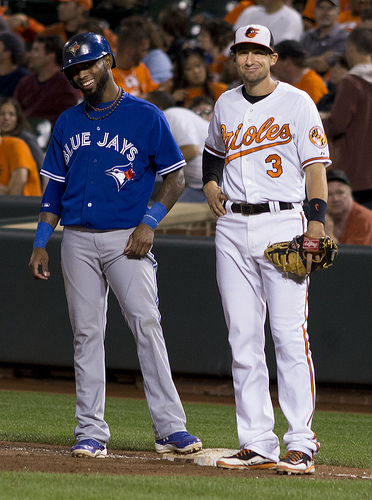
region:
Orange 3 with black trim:
[260, 148, 287, 187]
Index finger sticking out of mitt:
[298, 248, 316, 276]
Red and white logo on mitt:
[298, 237, 320, 252]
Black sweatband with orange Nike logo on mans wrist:
[304, 197, 328, 224]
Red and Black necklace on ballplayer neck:
[76, 86, 132, 123]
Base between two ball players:
[161, 433, 282, 478]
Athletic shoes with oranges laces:
[215, 427, 321, 480]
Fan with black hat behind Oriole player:
[322, 166, 369, 242]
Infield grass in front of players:
[4, 468, 369, 497]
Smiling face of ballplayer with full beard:
[48, 27, 134, 112]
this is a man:
[214, 30, 348, 310]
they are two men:
[32, 27, 315, 442]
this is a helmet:
[65, 38, 96, 62]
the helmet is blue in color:
[83, 37, 102, 48]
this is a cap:
[238, 24, 273, 48]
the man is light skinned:
[254, 72, 271, 82]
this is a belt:
[234, 200, 266, 213]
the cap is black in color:
[328, 169, 345, 176]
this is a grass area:
[325, 404, 364, 458]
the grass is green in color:
[181, 474, 218, 491]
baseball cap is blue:
[57, 35, 146, 73]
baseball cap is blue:
[51, 29, 140, 106]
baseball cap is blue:
[61, 34, 101, 102]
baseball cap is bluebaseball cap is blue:
[46, 25, 143, 125]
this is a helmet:
[56, 31, 110, 63]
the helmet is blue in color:
[68, 38, 101, 55]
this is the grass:
[53, 472, 114, 497]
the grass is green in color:
[94, 474, 136, 498]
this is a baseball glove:
[271, 232, 336, 267]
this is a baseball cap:
[234, 26, 271, 40]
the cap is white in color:
[234, 29, 243, 39]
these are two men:
[24, 28, 332, 466]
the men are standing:
[39, 26, 349, 490]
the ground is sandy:
[16, 449, 45, 466]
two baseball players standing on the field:
[8, 10, 352, 486]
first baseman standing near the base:
[192, 22, 331, 476]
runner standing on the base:
[7, 22, 203, 459]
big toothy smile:
[80, 79, 97, 88]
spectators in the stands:
[0, 0, 370, 239]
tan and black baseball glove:
[259, 227, 342, 285]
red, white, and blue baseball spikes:
[54, 418, 211, 471]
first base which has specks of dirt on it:
[163, 433, 247, 476]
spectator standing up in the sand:
[322, 29, 370, 217]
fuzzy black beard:
[78, 67, 110, 105]